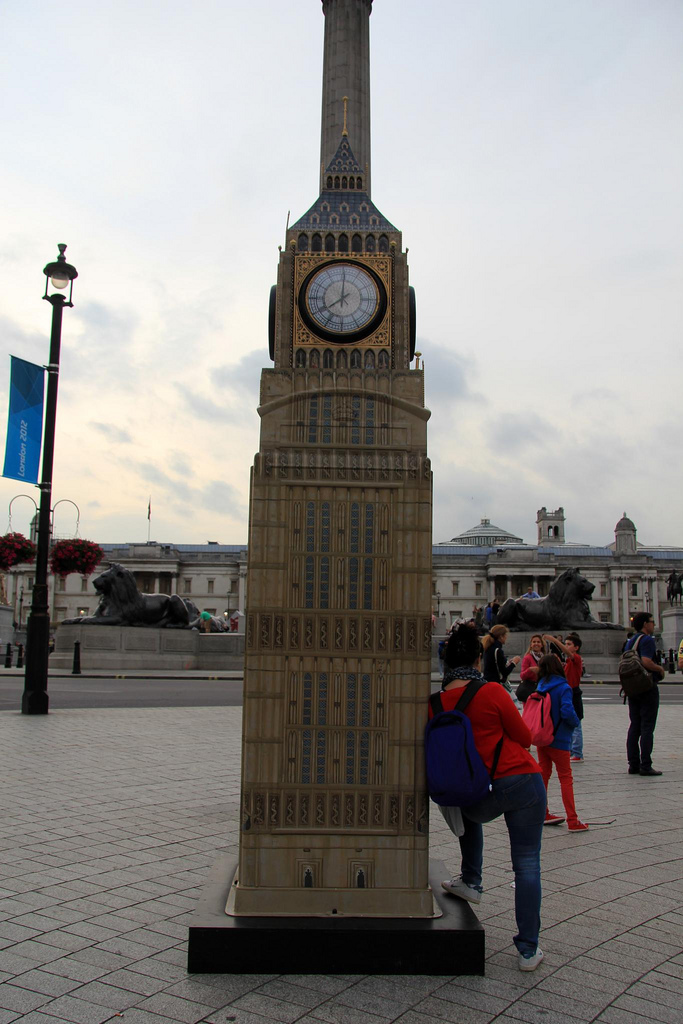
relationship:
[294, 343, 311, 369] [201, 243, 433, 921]
window on building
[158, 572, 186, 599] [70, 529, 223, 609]
window on building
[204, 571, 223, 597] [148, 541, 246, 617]
window on building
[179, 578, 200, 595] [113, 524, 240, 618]
window on a building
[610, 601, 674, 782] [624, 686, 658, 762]
man wears pants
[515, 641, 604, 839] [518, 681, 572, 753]
girl carry backpack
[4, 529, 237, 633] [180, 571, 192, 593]
building has window